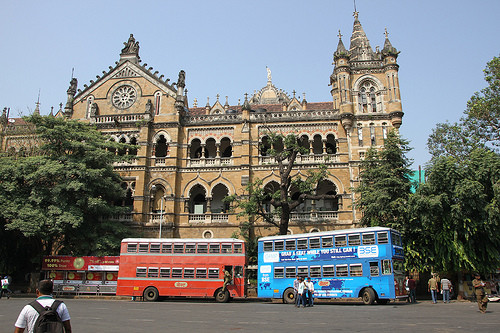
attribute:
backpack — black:
[30, 305, 75, 332]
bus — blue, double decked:
[252, 227, 410, 302]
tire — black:
[359, 285, 376, 306]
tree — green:
[0, 98, 132, 293]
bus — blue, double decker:
[254, 221, 413, 307]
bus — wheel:
[246, 229, 413, 326]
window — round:
[117, 74, 170, 126]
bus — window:
[253, 217, 420, 311]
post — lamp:
[150, 192, 173, 236]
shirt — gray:
[442, 279, 453, 291]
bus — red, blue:
[115, 235, 249, 302]